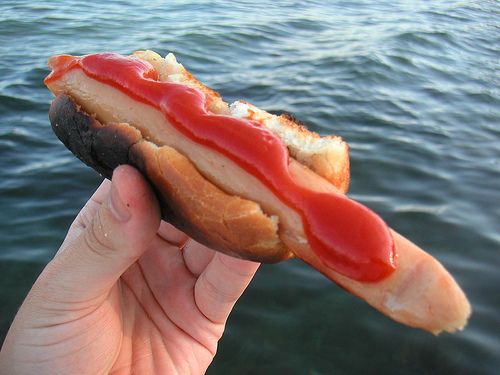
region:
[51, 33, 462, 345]
a sandwich with a red sauce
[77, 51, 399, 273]
The line of ketchup on the hot dog.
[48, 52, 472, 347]
The long hot dog on the bun.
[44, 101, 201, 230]
The burned and toasted part of the hot dog bun.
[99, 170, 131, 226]
The person's nail on their thumb.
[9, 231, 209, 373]
The palm of the person's hand.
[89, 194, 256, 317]
The person's fingers holding the hot dog.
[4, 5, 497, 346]
The water in the background.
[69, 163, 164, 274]
The person's thumb holding the hot dog.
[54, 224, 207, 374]
The wrinkles of the person's palm.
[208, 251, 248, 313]
The lines on the person's pinky finger.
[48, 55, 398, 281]
ketchup on a hotdog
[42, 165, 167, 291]
a thumb holding onto a bun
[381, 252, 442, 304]
a mark on the end of a hotdog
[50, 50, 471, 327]
a hotdog protruding from a bun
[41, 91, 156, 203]
a burn mark on a bun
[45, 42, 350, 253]
a bun holding a hotdog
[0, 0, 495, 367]
dark blue water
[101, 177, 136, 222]
a thumbnail on a thumb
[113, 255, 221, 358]
creases in the palm of a hand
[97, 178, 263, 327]
fingers supporting a bun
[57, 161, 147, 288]
Thumb of the person holding the hot dog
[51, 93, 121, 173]
Burnt part of a hotdog bun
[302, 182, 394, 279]
The ketchup on top of a hot dog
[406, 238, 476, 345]
The tip of the hotdog that's too big for the bun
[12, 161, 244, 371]
The hand holding a hotdog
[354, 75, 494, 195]
Water that is behind the hotdog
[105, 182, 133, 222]
The thumb nail on the thumb of the person holding a hot dog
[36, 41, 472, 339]
The hot dog in a bun with ketchup on top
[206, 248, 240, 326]
part of the pinky holding a hot dog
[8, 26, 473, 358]
A hand holding a hot dog over water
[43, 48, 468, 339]
a very long hot dog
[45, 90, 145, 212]
the burnt part of the bun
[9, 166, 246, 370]
the hand holding the hot dog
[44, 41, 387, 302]
the ketchup on the hot dog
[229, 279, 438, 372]
the darkest part of the water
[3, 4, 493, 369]
the water next to the man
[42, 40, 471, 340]
a hot dog to be eaten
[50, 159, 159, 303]
the man's thumb propping up the hot dog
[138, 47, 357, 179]
the rest of the bun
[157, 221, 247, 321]
the person's fingers